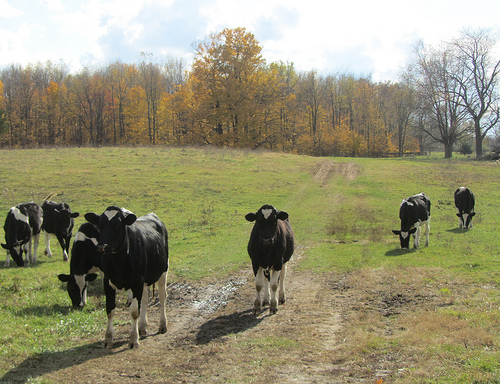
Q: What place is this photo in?
A: It is at the field.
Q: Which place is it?
A: It is a field.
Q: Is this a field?
A: Yes, it is a field.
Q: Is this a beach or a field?
A: It is a field.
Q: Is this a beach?
A: No, it is a field.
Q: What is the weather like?
A: It is clear.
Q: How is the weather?
A: It is clear.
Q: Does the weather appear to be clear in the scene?
A: Yes, it is clear.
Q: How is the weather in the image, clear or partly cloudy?
A: It is clear.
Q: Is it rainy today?
A: No, it is clear.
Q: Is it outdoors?
A: Yes, it is outdoors.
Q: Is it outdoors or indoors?
A: It is outdoors.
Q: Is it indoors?
A: No, it is outdoors.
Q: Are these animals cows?
A: Yes, all the animals are cows.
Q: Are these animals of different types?
A: No, all the animals are cows.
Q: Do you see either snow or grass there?
A: Yes, there is grass.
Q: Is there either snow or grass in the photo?
A: Yes, there is grass.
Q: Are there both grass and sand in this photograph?
A: No, there is grass but no sand.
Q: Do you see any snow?
A: No, there is no snow.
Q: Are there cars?
A: No, there are no cars.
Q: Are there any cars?
A: No, there are no cars.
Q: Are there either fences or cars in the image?
A: No, there are no cars or fences.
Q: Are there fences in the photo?
A: No, there are no fences.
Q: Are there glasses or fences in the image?
A: No, there are no fences or glasses.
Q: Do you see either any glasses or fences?
A: No, there are no fences or glasses.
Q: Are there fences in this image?
A: No, there are no fences.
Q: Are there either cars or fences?
A: No, there are no fences or cars.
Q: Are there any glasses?
A: No, there are no glasses.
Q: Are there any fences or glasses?
A: No, there are no glasses or fences.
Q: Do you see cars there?
A: No, there are no cars.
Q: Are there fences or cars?
A: No, there are no cars or fences.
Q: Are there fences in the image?
A: No, there are no fences.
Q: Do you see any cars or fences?
A: No, there are no fences or cars.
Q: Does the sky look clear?
A: Yes, the sky is clear.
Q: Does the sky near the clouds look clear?
A: Yes, the sky is clear.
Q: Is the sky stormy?
A: No, the sky is clear.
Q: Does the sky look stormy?
A: No, the sky is clear.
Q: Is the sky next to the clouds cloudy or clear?
A: The sky is clear.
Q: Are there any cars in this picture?
A: No, there are no cars.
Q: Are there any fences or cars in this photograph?
A: No, there are no cars or fences.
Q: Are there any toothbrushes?
A: No, there are no toothbrushes.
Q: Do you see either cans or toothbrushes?
A: No, there are no toothbrushes or cans.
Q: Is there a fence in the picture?
A: No, there are no fences.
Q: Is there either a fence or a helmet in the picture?
A: No, there are no fences or helmets.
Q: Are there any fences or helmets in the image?
A: No, there are no fences or helmets.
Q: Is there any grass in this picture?
A: Yes, there is grass.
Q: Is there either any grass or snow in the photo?
A: Yes, there is grass.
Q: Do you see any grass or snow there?
A: Yes, there is grass.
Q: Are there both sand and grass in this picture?
A: No, there is grass but no sand.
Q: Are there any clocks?
A: No, there are no clocks.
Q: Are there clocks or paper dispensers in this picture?
A: No, there are no clocks or paper dispensers.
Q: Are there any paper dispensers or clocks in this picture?
A: No, there are no clocks or paper dispensers.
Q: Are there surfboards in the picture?
A: No, there are no surfboards.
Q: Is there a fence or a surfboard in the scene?
A: No, there are no surfboards or fences.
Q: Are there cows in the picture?
A: Yes, there is a cow.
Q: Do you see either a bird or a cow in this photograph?
A: Yes, there is a cow.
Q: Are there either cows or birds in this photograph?
A: Yes, there is a cow.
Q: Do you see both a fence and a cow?
A: No, there is a cow but no fences.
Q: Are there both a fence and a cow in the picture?
A: No, there is a cow but no fences.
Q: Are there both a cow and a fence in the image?
A: No, there is a cow but no fences.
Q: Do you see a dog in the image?
A: No, there are no dogs.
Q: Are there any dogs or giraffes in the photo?
A: No, there are no dogs or giraffes.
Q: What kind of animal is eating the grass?
A: The animal is a cow.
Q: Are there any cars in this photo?
A: No, there are no cars.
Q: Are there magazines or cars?
A: No, there are no cars or magazines.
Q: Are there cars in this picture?
A: No, there are no cars.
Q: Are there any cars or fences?
A: No, there are no cars or fences.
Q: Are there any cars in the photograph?
A: No, there are no cars.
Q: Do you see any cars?
A: No, there are no cars.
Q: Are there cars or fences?
A: No, there are no cars or fences.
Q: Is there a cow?
A: Yes, there is a cow.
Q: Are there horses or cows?
A: Yes, there is a cow.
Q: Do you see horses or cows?
A: Yes, there is a cow.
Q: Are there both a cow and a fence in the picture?
A: No, there is a cow but no fences.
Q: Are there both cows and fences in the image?
A: No, there is a cow but no fences.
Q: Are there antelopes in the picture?
A: No, there are no antelopes.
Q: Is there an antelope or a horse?
A: No, there are no antelopes or horses.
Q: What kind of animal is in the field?
A: The animal is a cow.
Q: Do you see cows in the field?
A: Yes, there is a cow in the field.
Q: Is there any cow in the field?
A: Yes, there is a cow in the field.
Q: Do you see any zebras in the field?
A: No, there is a cow in the field.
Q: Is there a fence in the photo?
A: No, there are no fences.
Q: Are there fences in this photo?
A: No, there are no fences.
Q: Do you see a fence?
A: No, there are no fences.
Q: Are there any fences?
A: No, there are no fences.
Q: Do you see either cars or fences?
A: No, there are no cars or fences.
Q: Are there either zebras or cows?
A: Yes, there are cows.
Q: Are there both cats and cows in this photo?
A: No, there are cows but no cats.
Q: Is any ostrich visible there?
A: No, there are no ostriches.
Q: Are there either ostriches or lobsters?
A: No, there are no ostriches or lobsters.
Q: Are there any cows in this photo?
A: Yes, there are cows.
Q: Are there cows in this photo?
A: Yes, there are cows.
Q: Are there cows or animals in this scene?
A: Yes, there are cows.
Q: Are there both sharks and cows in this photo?
A: No, there are cows but no sharks.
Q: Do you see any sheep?
A: No, there are no sheep.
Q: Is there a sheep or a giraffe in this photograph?
A: No, there are no sheep or giraffes.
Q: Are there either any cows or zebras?
A: Yes, there is a cow.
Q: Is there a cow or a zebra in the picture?
A: Yes, there is a cow.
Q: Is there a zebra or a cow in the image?
A: Yes, there is a cow.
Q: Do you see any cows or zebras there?
A: Yes, there is a cow.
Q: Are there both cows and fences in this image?
A: No, there is a cow but no fences.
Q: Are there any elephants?
A: No, there are no elephants.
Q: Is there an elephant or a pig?
A: No, there are no elephants or pigs.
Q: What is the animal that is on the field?
A: The animal is a cow.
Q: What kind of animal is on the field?
A: The animal is a cow.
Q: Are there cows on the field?
A: Yes, there is a cow on the field.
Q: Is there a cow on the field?
A: Yes, there is a cow on the field.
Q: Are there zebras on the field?
A: No, there is a cow on the field.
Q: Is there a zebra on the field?
A: No, there is a cow on the field.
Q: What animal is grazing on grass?
A: The cow is grazing on grass.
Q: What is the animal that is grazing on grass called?
A: The animal is a cow.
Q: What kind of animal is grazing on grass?
A: The animal is a cow.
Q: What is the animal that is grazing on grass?
A: The animal is a cow.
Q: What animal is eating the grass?
A: The cow is eating the grass.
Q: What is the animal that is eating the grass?
A: The animal is a cow.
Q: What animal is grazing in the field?
A: The animal is a cow.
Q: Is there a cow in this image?
A: Yes, there is a cow.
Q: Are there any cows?
A: Yes, there is a cow.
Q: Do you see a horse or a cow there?
A: Yes, there is a cow.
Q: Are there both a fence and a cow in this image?
A: No, there is a cow but no fences.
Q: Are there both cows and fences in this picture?
A: No, there is a cow but no fences.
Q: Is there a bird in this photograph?
A: No, there are no birds.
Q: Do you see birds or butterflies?
A: No, there are no birds or butterflies.